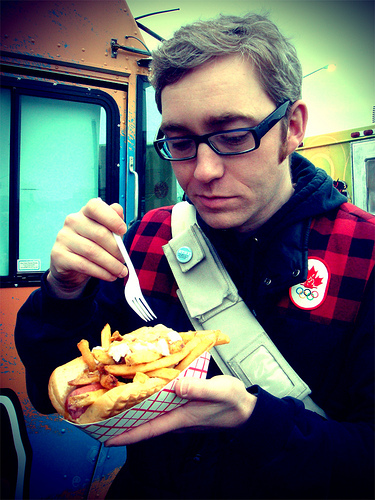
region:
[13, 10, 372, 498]
man eating food outdoors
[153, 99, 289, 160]
glasses with black frame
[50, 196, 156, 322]
white plastic fork in hand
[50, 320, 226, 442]
cardboard container of food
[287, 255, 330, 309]
fabric patch with emblem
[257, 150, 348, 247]
hood resting on shoulder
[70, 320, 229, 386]
pile of french fries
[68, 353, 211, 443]
red lines on white container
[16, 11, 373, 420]
strap across man's chest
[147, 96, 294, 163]
a man's black glasses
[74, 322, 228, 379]
french fries on a hotdog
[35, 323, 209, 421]
hotdog in a container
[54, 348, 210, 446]
paper container of food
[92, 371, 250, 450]
hand holding a container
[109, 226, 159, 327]
white plastic fork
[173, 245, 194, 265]
button on a strap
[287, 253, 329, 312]
patch with olympic logo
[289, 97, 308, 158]
man's left ear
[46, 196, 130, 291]
man's right hand holding the fork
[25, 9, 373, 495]
A man holding food in a cardboard carrier.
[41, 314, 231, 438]
A hot dog with french fries.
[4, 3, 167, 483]
A bus behind the man.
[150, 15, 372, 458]
The tan strap of a bag around the man.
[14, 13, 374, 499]
The man wears a coat with an Olympics symbol on it.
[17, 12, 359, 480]
The man is using a plastic fork to eat the food.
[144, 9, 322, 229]
The man is wearing glasses.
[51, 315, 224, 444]
The hot dog is in a red and white container.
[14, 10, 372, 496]
The man is looking down at the food in his hand.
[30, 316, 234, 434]
The container holds a hot dog and french fries.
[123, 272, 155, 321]
the tines on the fork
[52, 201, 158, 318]
man's hand holding fork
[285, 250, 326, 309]
Olympic logo on man's jacket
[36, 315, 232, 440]
Fries on top of a hotdog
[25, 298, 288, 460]
Man holding carton of food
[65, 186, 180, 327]
Man holding plastic fork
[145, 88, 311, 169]
Man wearing glasses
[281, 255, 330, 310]
Olympic patch on jacket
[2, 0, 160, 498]
Orange bus in the background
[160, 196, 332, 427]
Man wearing backpack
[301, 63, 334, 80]
Street lamp in the background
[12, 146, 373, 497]
Man wearing a jacket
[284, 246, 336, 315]
An Olympic patch.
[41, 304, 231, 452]
A hot dog with a lot of toppings.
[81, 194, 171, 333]
Plastic fork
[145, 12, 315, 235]
A man wearing glasses.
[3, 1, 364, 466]
Man standing next to a bus eating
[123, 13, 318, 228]
Man with long sideburns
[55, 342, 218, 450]
Paper food container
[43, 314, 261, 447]
Left hand holding food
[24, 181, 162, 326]
Righ hand holding a fork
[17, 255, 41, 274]
Sticker on a bus window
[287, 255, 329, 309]
white olympic patch with red border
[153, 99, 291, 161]
thick rimmed black eyeglasses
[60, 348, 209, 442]
red and white patterned paper food container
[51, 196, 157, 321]
hand holding white plastic disposable fork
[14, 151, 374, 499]
blue coat with red and black checks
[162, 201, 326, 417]
thick tan strap with blue button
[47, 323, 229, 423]
hot dog on bun covered with french fries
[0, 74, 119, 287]
two pane window with thick black frame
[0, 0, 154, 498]
orange and blue painted metal structure